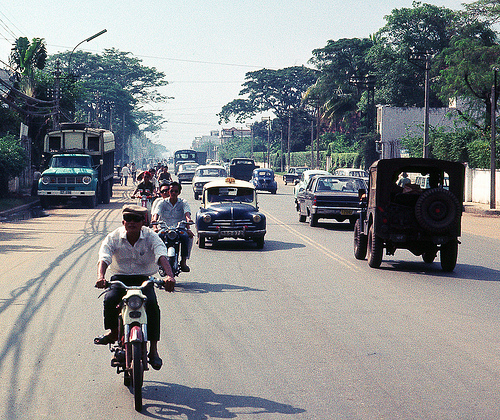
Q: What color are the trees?
A: Green.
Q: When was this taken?
A: Daytime.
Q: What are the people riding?
A: Motorcycles.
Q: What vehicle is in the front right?
A: Jeep.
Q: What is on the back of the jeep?
A: Spare tire.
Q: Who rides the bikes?
A: People.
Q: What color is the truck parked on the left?
A: Blue.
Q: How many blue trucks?
A: 1.